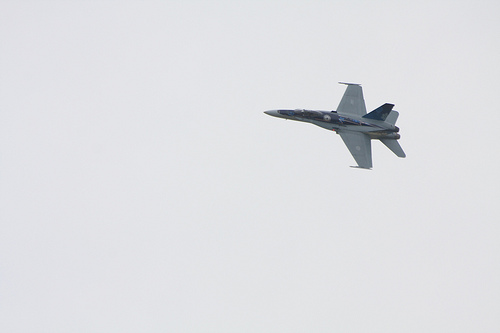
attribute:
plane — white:
[264, 82, 406, 169]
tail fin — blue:
[362, 102, 394, 121]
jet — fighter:
[223, 42, 456, 185]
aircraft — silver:
[265, 79, 404, 170]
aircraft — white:
[244, 61, 424, 203]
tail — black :
[364, 99, 400, 126]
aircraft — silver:
[267, 82, 412, 173]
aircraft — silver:
[259, 79, 441, 176]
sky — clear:
[6, 25, 139, 315]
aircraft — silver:
[259, 78, 409, 172]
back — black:
[264, 103, 344, 133]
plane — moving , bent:
[261, 77, 408, 172]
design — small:
[355, 143, 362, 152]